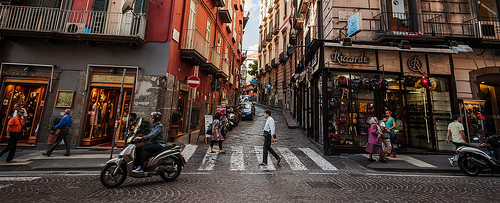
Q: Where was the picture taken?
A: In a city.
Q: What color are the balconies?
A: White and black.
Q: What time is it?
A: Daytime.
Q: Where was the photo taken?
A: Street.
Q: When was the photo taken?
A: Daytime.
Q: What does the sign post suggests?
A: No entry.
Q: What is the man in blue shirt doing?
A: Walking.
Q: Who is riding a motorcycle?
A: A man.